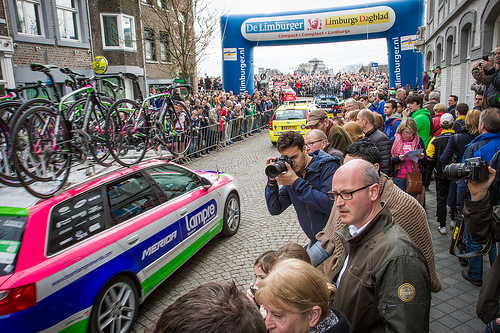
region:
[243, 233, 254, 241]
part of a road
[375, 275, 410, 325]
part of a coat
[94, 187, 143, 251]
part of a window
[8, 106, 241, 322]
the car is white with many colours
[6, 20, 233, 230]
it is carrying bicycles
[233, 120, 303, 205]
a man is taking a photo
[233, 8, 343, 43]
the finishing line is blue in colour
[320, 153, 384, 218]
the man has spectacles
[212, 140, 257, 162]
the floor is tiled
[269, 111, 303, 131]
the car is yellow in colour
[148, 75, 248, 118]
people are on the roadside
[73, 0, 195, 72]
the house has windows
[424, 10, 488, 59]
the house is white in colour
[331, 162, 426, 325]
this is a man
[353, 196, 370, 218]
the man is light skinned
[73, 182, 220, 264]
this is a car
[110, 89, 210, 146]
this is a bicycle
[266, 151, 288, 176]
this is a camera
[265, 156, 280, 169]
the camera is black in color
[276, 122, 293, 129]
the car is yellow in color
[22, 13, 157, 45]
this is the wall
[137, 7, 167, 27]
the wall is brown in color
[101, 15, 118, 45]
this is the window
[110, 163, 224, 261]
this is a car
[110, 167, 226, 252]
the car is colorful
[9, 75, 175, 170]
these are the bikes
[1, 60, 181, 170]
the bikes are on the car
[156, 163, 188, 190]
the window is closed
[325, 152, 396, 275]
this is a man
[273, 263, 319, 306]
this is the hair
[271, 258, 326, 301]
the hair is pale brown in color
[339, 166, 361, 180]
the man is light skinned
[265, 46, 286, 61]
this is the sky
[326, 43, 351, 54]
the sky is bright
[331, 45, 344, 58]
the sky has clouds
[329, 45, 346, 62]
the clouds are white in color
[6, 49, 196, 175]
these are some bicycles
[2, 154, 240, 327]
this is a car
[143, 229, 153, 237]
the car is white in color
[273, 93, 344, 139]
this is a race car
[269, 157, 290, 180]
this is a camera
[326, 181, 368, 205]
this is a pair of spectacles